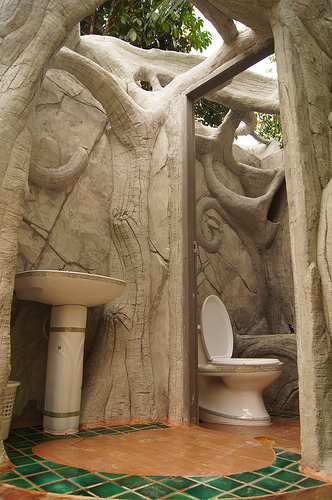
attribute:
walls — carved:
[0, 0, 332, 497]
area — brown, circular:
[81, 416, 301, 477]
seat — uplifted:
[178, 297, 264, 374]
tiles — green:
[23, 455, 237, 498]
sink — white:
[17, 266, 125, 430]